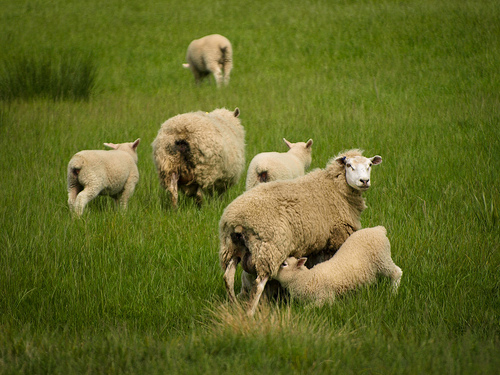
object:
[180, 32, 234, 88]
sheep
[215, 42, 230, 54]
tail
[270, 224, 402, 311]
lamb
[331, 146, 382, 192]
head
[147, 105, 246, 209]
sheep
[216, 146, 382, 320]
sheep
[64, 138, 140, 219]
sheep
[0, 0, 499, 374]
grass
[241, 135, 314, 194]
sheep